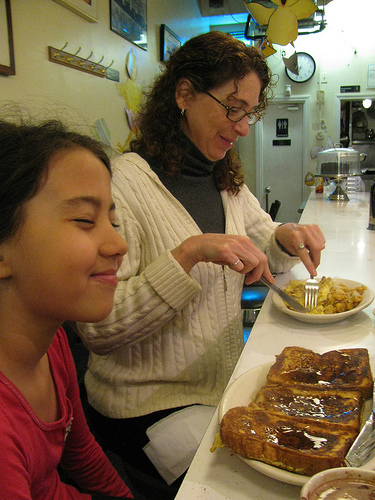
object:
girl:
[0, 117, 132, 499]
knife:
[251, 273, 310, 313]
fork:
[303, 264, 319, 311]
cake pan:
[313, 175, 357, 180]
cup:
[299, 467, 375, 500]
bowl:
[271, 274, 374, 324]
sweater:
[72, 151, 303, 421]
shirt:
[0, 325, 135, 498]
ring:
[297, 244, 304, 251]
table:
[173, 185, 374, 499]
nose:
[98, 229, 129, 258]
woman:
[75, 30, 325, 488]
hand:
[177, 231, 276, 286]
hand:
[275, 221, 325, 276]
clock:
[285, 50, 315, 84]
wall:
[0, 0, 210, 160]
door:
[262, 105, 303, 223]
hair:
[121, 31, 279, 197]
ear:
[174, 77, 192, 111]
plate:
[218, 358, 375, 485]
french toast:
[221, 402, 351, 476]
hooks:
[55, 41, 69, 56]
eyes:
[68, 214, 94, 229]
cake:
[320, 162, 349, 175]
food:
[310, 303, 324, 315]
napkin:
[142, 403, 218, 485]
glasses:
[202, 91, 260, 126]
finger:
[294, 240, 317, 276]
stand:
[327, 184, 350, 202]